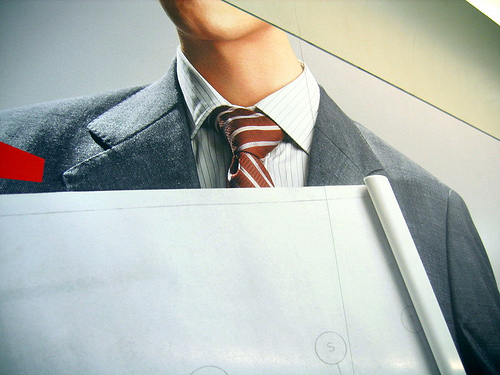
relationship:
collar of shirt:
[175, 46, 321, 156] [177, 46, 322, 186]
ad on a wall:
[2, 1, 499, 374] [224, 1, 499, 141]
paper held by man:
[1, 175, 467, 374] [1, 1, 500, 374]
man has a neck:
[1, 1, 500, 374] [180, 27, 303, 106]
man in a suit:
[1, 1, 500, 374] [1, 55, 500, 374]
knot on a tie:
[204, 104, 288, 161] [205, 105, 285, 187]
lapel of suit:
[61, 57, 201, 190] [1, 55, 500, 374]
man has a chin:
[1, 1, 500, 374] [160, 1, 266, 39]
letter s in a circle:
[323, 340, 338, 357] [315, 331, 347, 364]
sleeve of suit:
[447, 189, 500, 375] [1, 55, 500, 374]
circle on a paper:
[315, 331, 347, 364] [1, 175, 467, 374]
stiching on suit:
[317, 126, 366, 175] [1, 55, 500, 374]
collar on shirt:
[175, 46, 321, 156] [177, 46, 322, 186]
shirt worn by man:
[177, 46, 322, 186] [1, 1, 500, 374]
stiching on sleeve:
[317, 126, 366, 175] [447, 189, 500, 375]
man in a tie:
[1, 1, 500, 374] [205, 105, 285, 187]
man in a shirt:
[1, 1, 500, 374] [177, 46, 322, 186]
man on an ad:
[1, 1, 500, 374] [2, 1, 499, 374]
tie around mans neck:
[205, 105, 285, 187] [180, 27, 303, 106]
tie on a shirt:
[205, 105, 285, 187] [177, 46, 322, 186]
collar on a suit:
[175, 46, 321, 156] [1, 55, 500, 374]